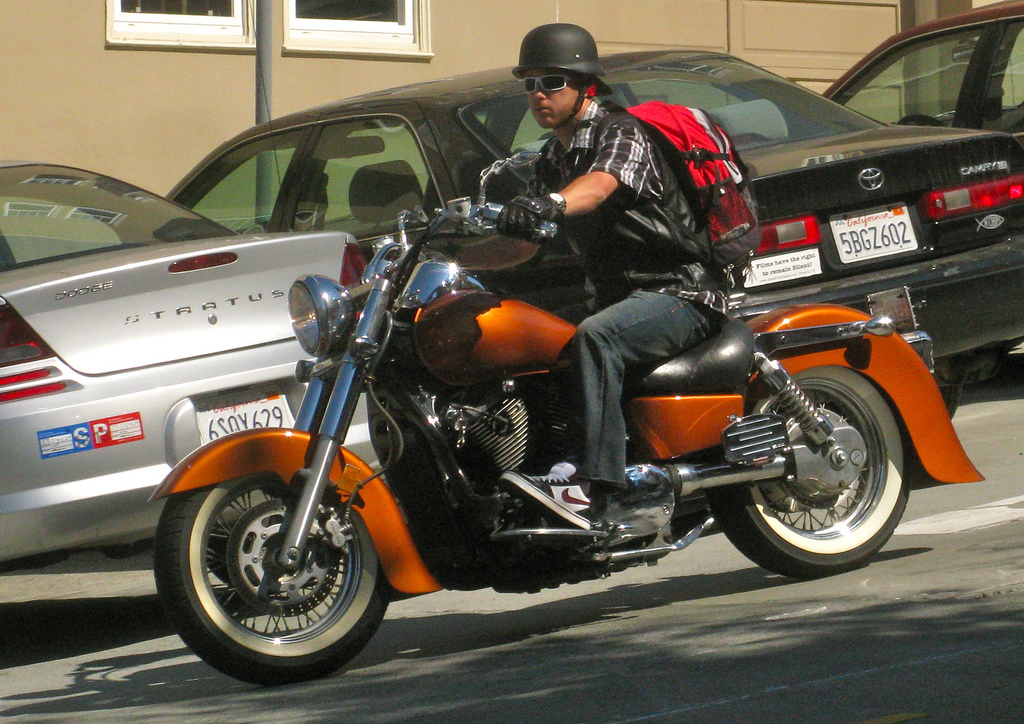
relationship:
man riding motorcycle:
[477, 17, 730, 530] [142, 142, 987, 687]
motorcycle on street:
[142, 142, 987, 687] [5, 370, 1023, 718]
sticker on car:
[35, 415, 149, 451] [1, 168, 302, 587]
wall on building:
[102, 65, 194, 158] [0, 0, 507, 160]